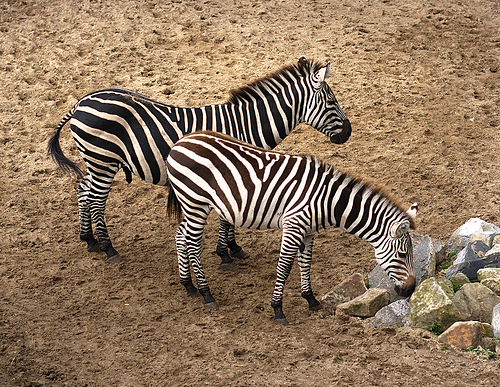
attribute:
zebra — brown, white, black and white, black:
[160, 125, 420, 328]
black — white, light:
[230, 150, 250, 180]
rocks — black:
[372, 182, 499, 317]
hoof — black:
[310, 302, 326, 311]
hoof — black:
[275, 313, 287, 325]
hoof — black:
[207, 299, 220, 311]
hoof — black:
[221, 258, 240, 271]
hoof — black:
[231, 245, 249, 258]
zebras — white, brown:
[26, 44, 439, 322]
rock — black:
[430, 316, 490, 354]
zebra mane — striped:
[209, 51, 309, 99]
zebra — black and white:
[122, 117, 496, 315]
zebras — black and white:
[42, 55, 421, 334]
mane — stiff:
[228, 55, 315, 102]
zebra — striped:
[140, 83, 437, 348]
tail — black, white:
[43, 100, 91, 194]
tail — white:
[160, 177, 187, 222]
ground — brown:
[2, 2, 499, 384]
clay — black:
[388, 115, 483, 174]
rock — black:
[405, 275, 465, 332]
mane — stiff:
[336, 163, 415, 228]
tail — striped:
[44, 104, 81, 184]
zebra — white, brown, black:
[47, 54, 353, 260]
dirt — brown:
[3, 3, 481, 382]